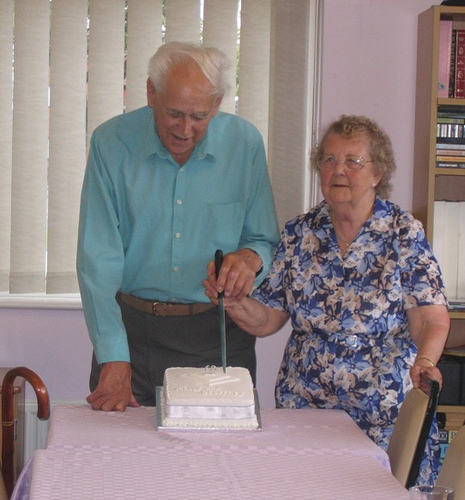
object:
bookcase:
[413, 5, 465, 358]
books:
[436, 7, 454, 99]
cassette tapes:
[435, 162, 464, 168]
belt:
[117, 292, 219, 317]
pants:
[86, 300, 260, 413]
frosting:
[198, 381, 203, 382]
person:
[75, 41, 282, 413]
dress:
[253, 198, 452, 490]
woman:
[202, 115, 458, 499]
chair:
[383, 377, 440, 488]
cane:
[0, 366, 55, 499]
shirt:
[74, 109, 283, 366]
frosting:
[198, 386, 211, 399]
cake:
[154, 362, 262, 429]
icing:
[224, 394, 234, 402]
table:
[11, 404, 407, 500]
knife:
[210, 248, 229, 374]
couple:
[75, 43, 447, 487]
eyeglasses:
[315, 153, 376, 173]